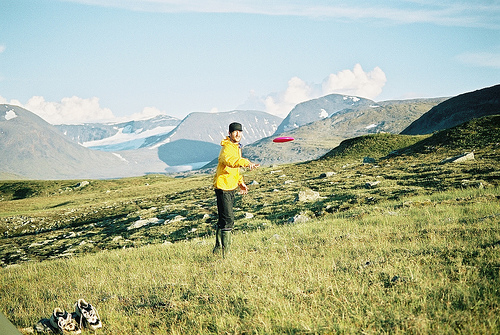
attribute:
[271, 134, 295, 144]
frisbee — pink, purple, red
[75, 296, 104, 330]
shoe — white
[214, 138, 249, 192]
jacket — yellow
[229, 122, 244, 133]
hat — black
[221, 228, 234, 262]
boot — tall, black, green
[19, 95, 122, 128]
cloud — fluffy, white, tufty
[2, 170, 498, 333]
field — grassy